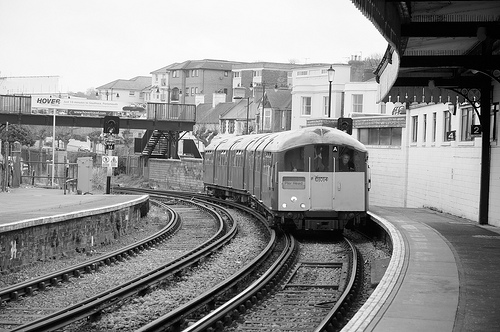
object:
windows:
[192, 70, 196, 77]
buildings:
[148, 57, 233, 132]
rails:
[214, 282, 227, 290]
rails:
[136, 277, 143, 285]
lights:
[290, 196, 298, 203]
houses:
[287, 61, 350, 130]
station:
[0, 0, 500, 332]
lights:
[300, 203, 306, 208]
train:
[200, 125, 373, 236]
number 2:
[471, 124, 481, 135]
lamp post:
[328, 81, 333, 117]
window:
[284, 143, 306, 172]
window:
[312, 144, 331, 172]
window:
[338, 146, 355, 172]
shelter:
[347, 0, 498, 103]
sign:
[444, 130, 457, 142]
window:
[412, 115, 418, 142]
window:
[424, 114, 426, 143]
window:
[432, 111, 436, 143]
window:
[443, 110, 451, 142]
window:
[457, 105, 477, 141]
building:
[403, 99, 500, 226]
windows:
[195, 87, 198, 94]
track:
[2, 185, 361, 330]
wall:
[370, 136, 495, 227]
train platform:
[410, 213, 480, 305]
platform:
[338, 203, 498, 332]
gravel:
[218, 193, 360, 312]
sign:
[282, 176, 306, 189]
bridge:
[0, 112, 194, 131]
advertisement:
[30, 97, 124, 112]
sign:
[231, 97, 399, 129]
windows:
[261, 153, 271, 168]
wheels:
[267, 216, 278, 228]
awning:
[369, 19, 490, 105]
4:
[446, 121, 455, 142]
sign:
[31, 96, 123, 112]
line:
[338, 210, 405, 330]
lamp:
[326, 64, 336, 82]